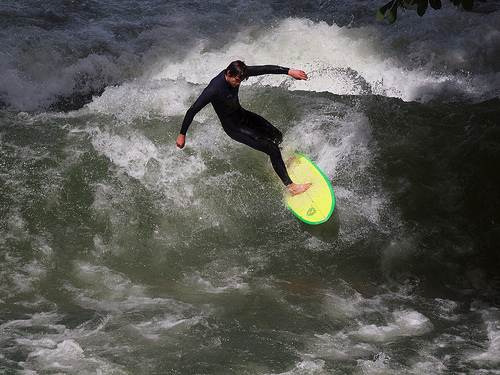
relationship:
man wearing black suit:
[175, 60, 313, 197] [177, 64, 292, 185]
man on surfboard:
[175, 60, 313, 197] [280, 152, 338, 226]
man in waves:
[175, 60, 313, 197] [0, 0, 499, 290]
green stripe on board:
[279, 152, 335, 225] [288, 155, 339, 237]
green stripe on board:
[279, 152, 335, 225] [278, 149, 336, 231]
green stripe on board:
[279, 152, 335, 225] [277, 149, 340, 229]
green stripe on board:
[286, 152, 335, 224] [269, 147, 337, 227]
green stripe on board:
[279, 152, 335, 225] [244, 122, 359, 257]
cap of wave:
[87, 75, 204, 131] [9, 78, 495, 294]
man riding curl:
[175, 60, 313, 197] [3, 73, 497, 164]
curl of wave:
[3, 73, 497, 164] [3, 68, 498, 281]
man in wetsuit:
[175, 60, 313, 197] [187, 67, 294, 181]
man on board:
[175, 60, 313, 197] [270, 149, 335, 225]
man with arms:
[175, 60, 313, 197] [173, 62, 310, 150]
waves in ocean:
[6, 78, 497, 227] [8, 9, 495, 371]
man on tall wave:
[175, 60, 313, 197] [1, 17, 499, 302]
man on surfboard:
[158, 23, 399, 280] [280, 152, 338, 226]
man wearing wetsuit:
[175, 60, 313, 197] [187, 89, 317, 193]